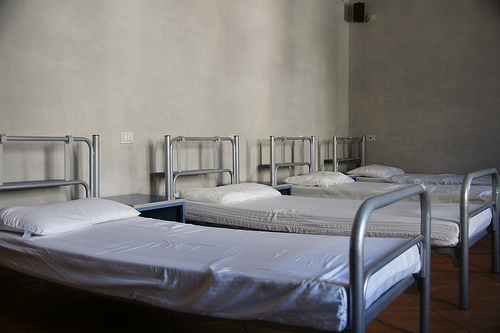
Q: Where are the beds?
A: Inside The room.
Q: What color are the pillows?
A: White.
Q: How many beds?
A: 4.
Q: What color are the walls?
A: Grey.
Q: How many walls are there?
A: 2.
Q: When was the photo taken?
A: Daytime.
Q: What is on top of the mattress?
A: Pillows and sheets.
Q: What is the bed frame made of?
A: Metal.